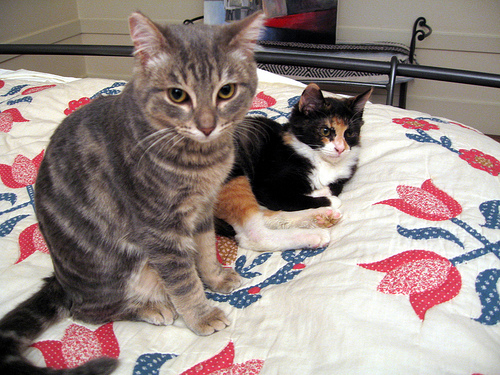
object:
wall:
[1, 3, 495, 129]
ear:
[124, 11, 169, 61]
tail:
[1, 274, 121, 375]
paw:
[185, 302, 234, 339]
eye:
[162, 85, 191, 105]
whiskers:
[135, 124, 182, 170]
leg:
[160, 259, 231, 337]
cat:
[212, 83, 373, 251]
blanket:
[2, 64, 499, 374]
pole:
[4, 38, 497, 91]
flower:
[372, 175, 461, 226]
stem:
[392, 225, 465, 247]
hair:
[133, 39, 150, 54]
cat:
[0, 8, 264, 373]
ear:
[224, 10, 264, 47]